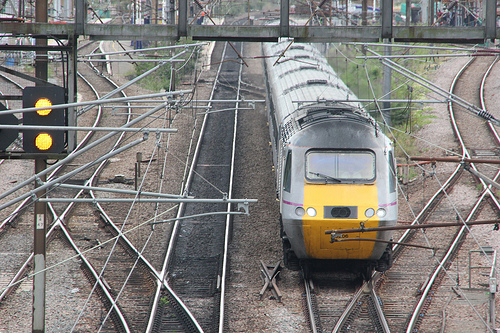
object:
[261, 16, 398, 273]
train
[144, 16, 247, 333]
tracks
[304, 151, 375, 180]
windshield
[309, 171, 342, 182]
wiper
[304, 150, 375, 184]
window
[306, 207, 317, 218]
light